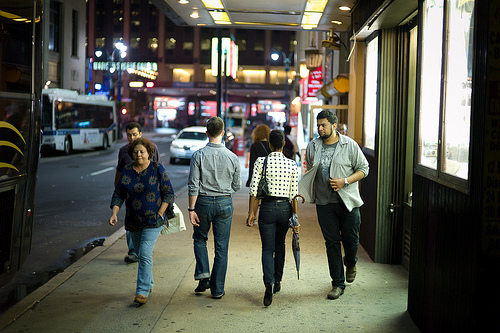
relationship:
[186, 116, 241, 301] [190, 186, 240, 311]
people wearing jeans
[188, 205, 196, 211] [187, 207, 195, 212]
watch on left wrist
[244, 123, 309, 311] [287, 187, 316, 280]
woman carrying umbrella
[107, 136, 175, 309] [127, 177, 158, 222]
people wearing sweater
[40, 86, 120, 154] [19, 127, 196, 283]
tour bus on a street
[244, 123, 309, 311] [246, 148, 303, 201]
woman wearing shirt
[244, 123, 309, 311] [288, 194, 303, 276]
woman holding umbrella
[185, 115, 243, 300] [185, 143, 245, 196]
man wearing shirt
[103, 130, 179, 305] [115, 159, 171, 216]
woman wearing shirt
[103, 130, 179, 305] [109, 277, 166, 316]
woman wearing shoes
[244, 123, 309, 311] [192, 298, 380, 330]
woman walking on sidewalk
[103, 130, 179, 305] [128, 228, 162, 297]
woman wearing jeans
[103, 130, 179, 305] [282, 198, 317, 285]
woman carrying umbrella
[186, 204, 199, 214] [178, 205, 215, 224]
wristwatch on wrist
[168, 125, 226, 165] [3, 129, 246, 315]
vehicle on side of street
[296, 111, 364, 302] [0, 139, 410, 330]
people walking on sidewalk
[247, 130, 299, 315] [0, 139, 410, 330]
people walking on sidewalk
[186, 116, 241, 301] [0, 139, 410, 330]
people walking on sidewalk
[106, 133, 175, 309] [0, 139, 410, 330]
people walking on sidewalk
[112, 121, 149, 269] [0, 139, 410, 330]
people walking on sidewalk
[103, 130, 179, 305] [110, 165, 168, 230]
woman wearing sweater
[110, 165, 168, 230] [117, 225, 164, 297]
sweater wearing jeans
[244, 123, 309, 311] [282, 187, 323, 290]
woman walking with umbrella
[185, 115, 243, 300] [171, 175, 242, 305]
man wearing jeans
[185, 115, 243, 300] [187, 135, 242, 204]
man wearing shirt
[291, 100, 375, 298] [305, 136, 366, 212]
man wearing two shirts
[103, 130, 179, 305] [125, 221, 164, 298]
woman wearing jeans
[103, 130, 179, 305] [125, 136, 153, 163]
woman with hair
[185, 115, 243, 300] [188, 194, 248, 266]
man wearing jeans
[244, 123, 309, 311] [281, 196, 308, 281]
woman holding umbrella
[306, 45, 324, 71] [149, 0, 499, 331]
street light attached to a building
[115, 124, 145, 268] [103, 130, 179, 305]
man walking behind woman